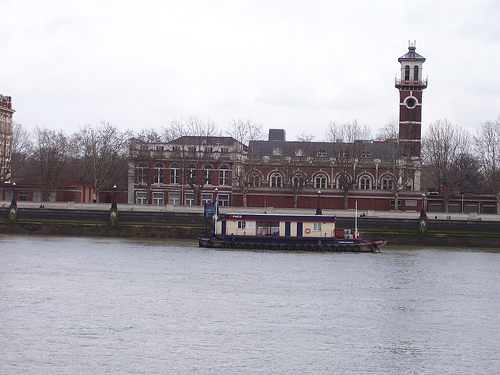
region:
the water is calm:
[87, 250, 383, 374]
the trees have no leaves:
[31, 94, 259, 204]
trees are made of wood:
[28, 149, 185, 235]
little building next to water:
[192, 167, 437, 298]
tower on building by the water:
[373, 50, 471, 212]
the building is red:
[112, 78, 498, 272]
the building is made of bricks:
[124, 83, 450, 285]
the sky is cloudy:
[91, 36, 421, 198]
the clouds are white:
[79, 33, 339, 155]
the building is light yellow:
[214, 203, 404, 259]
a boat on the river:
[193, 206, 393, 255]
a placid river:
[1, 228, 498, 374]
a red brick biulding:
[128, 134, 426, 210]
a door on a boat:
[296, 215, 306, 239]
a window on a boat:
[310, 220, 325, 234]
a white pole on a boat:
[351, 194, 362, 237]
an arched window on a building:
[311, 168, 328, 191]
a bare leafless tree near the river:
[422, 118, 464, 208]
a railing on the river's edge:
[4, 196, 208, 215]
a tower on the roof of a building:
[395, 33, 432, 154]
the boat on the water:
[191, 195, 407, 266]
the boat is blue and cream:
[184, 193, 389, 259]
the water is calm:
[177, 274, 403, 354]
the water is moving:
[171, 252, 418, 333]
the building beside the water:
[119, 127, 436, 203]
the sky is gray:
[106, 22, 282, 87]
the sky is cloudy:
[88, 22, 265, 93]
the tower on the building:
[392, 43, 445, 145]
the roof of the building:
[161, 132, 387, 165]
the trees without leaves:
[22, 128, 499, 200]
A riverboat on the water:
[197, 200, 395, 257]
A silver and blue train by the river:
[1, 192, 498, 249]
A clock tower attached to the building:
[390, 36, 430, 159]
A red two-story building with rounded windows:
[115, 123, 430, 215]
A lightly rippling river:
[2, 203, 499, 372]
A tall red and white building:
[0, 90, 20, 192]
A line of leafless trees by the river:
[3, 123, 492, 210]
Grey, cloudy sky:
[0, 0, 499, 120]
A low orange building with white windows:
[0, 175, 98, 205]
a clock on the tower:
[403, 95, 418, 110]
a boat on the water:
[194, 207, 386, 256]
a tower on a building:
[393, 44, 434, 140]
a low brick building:
[0, 176, 94, 204]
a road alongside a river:
[2, 197, 499, 223]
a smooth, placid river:
[2, 230, 497, 373]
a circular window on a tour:
[403, 95, 419, 110]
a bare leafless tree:
[28, 130, 68, 203]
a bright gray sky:
[2, 3, 497, 157]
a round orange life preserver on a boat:
[302, 225, 315, 236]